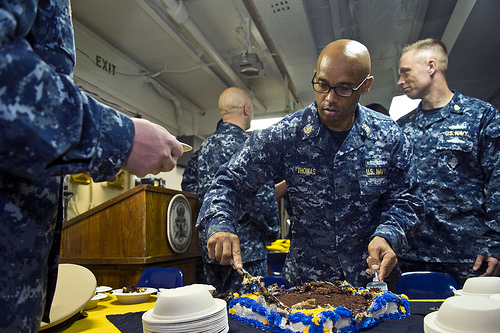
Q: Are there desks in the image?
A: Yes, there is a desk.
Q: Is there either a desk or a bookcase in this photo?
A: Yes, there is a desk.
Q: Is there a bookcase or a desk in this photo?
A: Yes, there is a desk.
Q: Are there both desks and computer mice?
A: No, there is a desk but no computer mice.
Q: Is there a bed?
A: No, there are no beds.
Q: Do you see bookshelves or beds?
A: No, there are no beds or bookshelves.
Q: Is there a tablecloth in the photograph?
A: Yes, there is a tablecloth.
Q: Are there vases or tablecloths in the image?
A: Yes, there is a tablecloth.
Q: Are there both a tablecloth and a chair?
A: Yes, there are both a tablecloth and a chair.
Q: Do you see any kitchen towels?
A: No, there are no kitchen towels.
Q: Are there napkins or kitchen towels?
A: No, there are no kitchen towels or napkins.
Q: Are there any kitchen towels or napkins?
A: No, there are no kitchen towels or napkins.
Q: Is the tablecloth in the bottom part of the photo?
A: Yes, the tablecloth is in the bottom of the image.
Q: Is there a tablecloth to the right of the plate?
A: Yes, there is a tablecloth to the right of the plate.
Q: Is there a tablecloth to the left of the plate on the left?
A: No, the tablecloth is to the right of the plate.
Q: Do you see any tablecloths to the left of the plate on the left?
A: No, the tablecloth is to the right of the plate.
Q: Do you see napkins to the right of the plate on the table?
A: No, there is a tablecloth to the right of the plate.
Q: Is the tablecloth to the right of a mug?
A: No, the tablecloth is to the right of a plate.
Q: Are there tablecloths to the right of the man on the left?
A: Yes, there is a tablecloth to the right of the man.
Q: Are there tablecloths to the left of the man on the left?
A: No, the tablecloth is to the right of the man.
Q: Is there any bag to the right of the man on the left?
A: No, there is a tablecloth to the right of the man.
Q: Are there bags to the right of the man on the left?
A: No, there is a tablecloth to the right of the man.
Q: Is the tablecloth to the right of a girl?
A: No, the tablecloth is to the right of the man.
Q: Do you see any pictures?
A: No, there are no pictures.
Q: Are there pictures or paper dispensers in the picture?
A: No, there are no pictures or paper dispensers.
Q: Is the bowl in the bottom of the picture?
A: Yes, the bowl is in the bottom of the image.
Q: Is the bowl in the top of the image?
A: No, the bowl is in the bottom of the image.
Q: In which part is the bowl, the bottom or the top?
A: The bowl is in the bottom of the image.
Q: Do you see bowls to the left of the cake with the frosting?
A: Yes, there is a bowl to the left of the cake.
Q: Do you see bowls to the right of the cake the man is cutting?
A: No, the bowl is to the left of the cake.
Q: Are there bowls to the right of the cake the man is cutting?
A: No, the bowl is to the left of the cake.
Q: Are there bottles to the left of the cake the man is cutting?
A: No, there is a bowl to the left of the cake.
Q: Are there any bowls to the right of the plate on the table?
A: Yes, there is a bowl to the right of the plate.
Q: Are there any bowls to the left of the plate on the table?
A: No, the bowl is to the right of the plate.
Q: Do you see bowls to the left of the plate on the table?
A: No, the bowl is to the right of the plate.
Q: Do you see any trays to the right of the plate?
A: No, there is a bowl to the right of the plate.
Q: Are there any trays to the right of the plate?
A: No, there is a bowl to the right of the plate.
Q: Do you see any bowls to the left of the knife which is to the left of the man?
A: Yes, there is a bowl to the left of the knife.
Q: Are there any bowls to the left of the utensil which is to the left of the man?
A: Yes, there is a bowl to the left of the knife.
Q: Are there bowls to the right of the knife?
A: No, the bowl is to the left of the knife.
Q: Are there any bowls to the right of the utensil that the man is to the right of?
A: No, the bowl is to the left of the knife.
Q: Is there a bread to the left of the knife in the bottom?
A: No, there is a bowl to the left of the knife.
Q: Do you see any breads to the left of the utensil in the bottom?
A: No, there is a bowl to the left of the knife.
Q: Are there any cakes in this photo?
A: Yes, there is a cake.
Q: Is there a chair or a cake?
A: Yes, there is a cake.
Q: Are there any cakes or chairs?
A: Yes, there is a cake.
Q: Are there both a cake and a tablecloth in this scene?
A: Yes, there are both a cake and a tablecloth.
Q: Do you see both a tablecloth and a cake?
A: Yes, there are both a cake and a tablecloth.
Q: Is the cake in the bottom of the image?
A: Yes, the cake is in the bottom of the image.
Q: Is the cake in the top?
A: No, the cake is in the bottom of the image.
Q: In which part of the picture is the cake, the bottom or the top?
A: The cake is in the bottom of the image.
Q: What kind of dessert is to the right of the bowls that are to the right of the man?
A: The dessert is a cake.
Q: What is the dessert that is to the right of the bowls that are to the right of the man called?
A: The dessert is a cake.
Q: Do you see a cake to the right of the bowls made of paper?
A: Yes, there is a cake to the right of the bowls.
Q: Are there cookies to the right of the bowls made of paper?
A: No, there is a cake to the right of the bowls.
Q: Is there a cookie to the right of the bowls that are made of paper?
A: No, there is a cake to the right of the bowls.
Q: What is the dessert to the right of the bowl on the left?
A: The dessert is a cake.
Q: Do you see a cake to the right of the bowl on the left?
A: Yes, there is a cake to the right of the bowl.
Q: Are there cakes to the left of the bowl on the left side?
A: No, the cake is to the right of the bowl.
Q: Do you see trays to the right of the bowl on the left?
A: No, there is a cake to the right of the bowl.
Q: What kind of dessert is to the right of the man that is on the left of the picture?
A: The dessert is a cake.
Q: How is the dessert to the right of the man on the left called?
A: The dessert is a cake.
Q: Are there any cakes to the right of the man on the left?
A: Yes, there is a cake to the right of the man.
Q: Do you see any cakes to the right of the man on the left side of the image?
A: Yes, there is a cake to the right of the man.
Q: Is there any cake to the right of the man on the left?
A: Yes, there is a cake to the right of the man.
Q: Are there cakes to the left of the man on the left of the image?
A: No, the cake is to the right of the man.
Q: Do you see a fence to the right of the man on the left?
A: No, there is a cake to the right of the man.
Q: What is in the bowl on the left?
A: The cake is in the bowl.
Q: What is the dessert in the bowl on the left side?
A: The dessert is a cake.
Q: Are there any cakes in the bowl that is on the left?
A: Yes, there is a cake in the bowl.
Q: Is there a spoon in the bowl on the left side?
A: No, there is a cake in the bowl.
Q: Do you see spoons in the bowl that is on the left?
A: No, there is a cake in the bowl.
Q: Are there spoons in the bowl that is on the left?
A: No, there is a cake in the bowl.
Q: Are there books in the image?
A: No, there are no books.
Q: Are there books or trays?
A: No, there are no books or trays.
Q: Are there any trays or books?
A: No, there are no books or trays.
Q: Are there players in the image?
A: No, there are no players.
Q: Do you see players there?
A: No, there are no players.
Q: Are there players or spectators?
A: No, there are no players or spectators.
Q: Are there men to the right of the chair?
A: Yes, there is a man to the right of the chair.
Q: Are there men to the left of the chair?
A: No, the man is to the right of the chair.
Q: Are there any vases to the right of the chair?
A: No, there is a man to the right of the chair.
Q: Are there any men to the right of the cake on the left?
A: Yes, there is a man to the right of the cake.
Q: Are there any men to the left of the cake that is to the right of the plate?
A: No, the man is to the right of the cake.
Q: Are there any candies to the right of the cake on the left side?
A: No, there is a man to the right of the cake.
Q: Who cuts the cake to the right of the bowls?
A: The man cuts the cake.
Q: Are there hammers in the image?
A: No, there are no hammers.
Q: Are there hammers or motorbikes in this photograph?
A: No, there are no hammers or motorbikes.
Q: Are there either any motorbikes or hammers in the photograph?
A: No, there are no hammers or motorbikes.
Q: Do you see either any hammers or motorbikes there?
A: No, there are no hammers or motorbikes.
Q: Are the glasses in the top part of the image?
A: Yes, the glasses are in the top of the image.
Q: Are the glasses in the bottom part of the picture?
A: No, the glasses are in the top of the image.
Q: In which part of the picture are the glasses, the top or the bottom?
A: The glasses are in the top of the image.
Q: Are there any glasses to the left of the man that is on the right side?
A: Yes, there are glasses to the left of the man.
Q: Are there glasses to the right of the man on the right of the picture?
A: No, the glasses are to the left of the man.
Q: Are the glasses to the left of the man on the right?
A: Yes, the glasses are to the left of the man.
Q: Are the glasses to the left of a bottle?
A: No, the glasses are to the left of the man.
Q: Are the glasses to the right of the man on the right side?
A: No, the glasses are to the left of the man.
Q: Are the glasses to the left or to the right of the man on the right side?
A: The glasses are to the left of the man.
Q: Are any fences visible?
A: No, there are no fences.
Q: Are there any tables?
A: Yes, there is a table.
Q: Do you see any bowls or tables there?
A: Yes, there is a table.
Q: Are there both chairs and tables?
A: Yes, there are both a table and a chair.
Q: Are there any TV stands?
A: No, there are no TV stands.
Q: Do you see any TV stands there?
A: No, there are no TV stands.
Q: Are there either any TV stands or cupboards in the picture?
A: No, there are no TV stands or cupboards.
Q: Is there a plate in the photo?
A: Yes, there is a plate.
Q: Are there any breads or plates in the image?
A: Yes, there is a plate.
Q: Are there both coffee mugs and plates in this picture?
A: No, there is a plate but no coffee mugs.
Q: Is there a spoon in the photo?
A: No, there are no spoons.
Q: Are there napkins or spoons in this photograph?
A: No, there are no spoons or napkins.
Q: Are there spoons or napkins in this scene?
A: No, there are no spoons or napkins.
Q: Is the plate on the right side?
A: No, the plate is on the left of the image.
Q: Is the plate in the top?
A: No, the plate is in the bottom of the image.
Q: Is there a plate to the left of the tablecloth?
A: Yes, there is a plate to the left of the tablecloth.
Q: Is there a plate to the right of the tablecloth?
A: No, the plate is to the left of the tablecloth.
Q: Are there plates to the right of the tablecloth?
A: No, the plate is to the left of the tablecloth.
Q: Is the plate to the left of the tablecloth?
A: Yes, the plate is to the left of the tablecloth.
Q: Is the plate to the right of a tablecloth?
A: No, the plate is to the left of a tablecloth.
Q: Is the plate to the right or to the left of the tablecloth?
A: The plate is to the left of the tablecloth.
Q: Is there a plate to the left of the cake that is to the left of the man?
A: Yes, there is a plate to the left of the cake.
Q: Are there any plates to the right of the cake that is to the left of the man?
A: No, the plate is to the left of the cake.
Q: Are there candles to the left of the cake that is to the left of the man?
A: No, there is a plate to the left of the cake.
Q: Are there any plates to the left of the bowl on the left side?
A: Yes, there is a plate to the left of the bowl.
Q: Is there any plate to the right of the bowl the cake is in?
A: No, the plate is to the left of the bowl.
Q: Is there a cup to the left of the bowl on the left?
A: No, there is a plate to the left of the bowl.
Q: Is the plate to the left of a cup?
A: No, the plate is to the left of the bowl.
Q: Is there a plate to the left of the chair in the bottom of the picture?
A: Yes, there is a plate to the left of the chair.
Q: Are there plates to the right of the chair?
A: No, the plate is to the left of the chair.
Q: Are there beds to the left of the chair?
A: No, there is a plate to the left of the chair.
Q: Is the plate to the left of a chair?
A: Yes, the plate is to the left of a chair.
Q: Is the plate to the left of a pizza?
A: No, the plate is to the left of a chair.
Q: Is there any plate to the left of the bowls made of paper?
A: Yes, there is a plate to the left of the bowls.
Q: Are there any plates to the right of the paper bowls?
A: No, the plate is to the left of the bowls.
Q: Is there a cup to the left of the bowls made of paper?
A: No, there is a plate to the left of the bowls.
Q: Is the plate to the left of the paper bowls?
A: Yes, the plate is to the left of the bowls.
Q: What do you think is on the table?
A: The plate is on the table.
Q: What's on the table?
A: The plate is on the table.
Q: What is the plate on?
A: The plate is on the table.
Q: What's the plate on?
A: The plate is on the table.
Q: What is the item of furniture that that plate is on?
A: The piece of furniture is a table.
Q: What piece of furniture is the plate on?
A: The plate is on the table.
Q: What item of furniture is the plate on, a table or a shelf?
A: The plate is on a table.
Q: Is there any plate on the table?
A: Yes, there is a plate on the table.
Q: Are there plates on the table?
A: Yes, there is a plate on the table.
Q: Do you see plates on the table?
A: Yes, there is a plate on the table.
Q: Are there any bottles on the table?
A: No, there is a plate on the table.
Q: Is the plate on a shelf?
A: No, the plate is on the table.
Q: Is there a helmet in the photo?
A: No, there are no helmets.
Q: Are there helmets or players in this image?
A: No, there are no helmets or players.